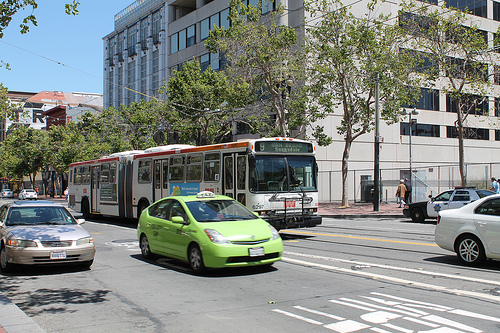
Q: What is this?
A: A city setting.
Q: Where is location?
A: A city street.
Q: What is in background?
A: A building.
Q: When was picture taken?
A: During daylight.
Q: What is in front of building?
A: Busses.